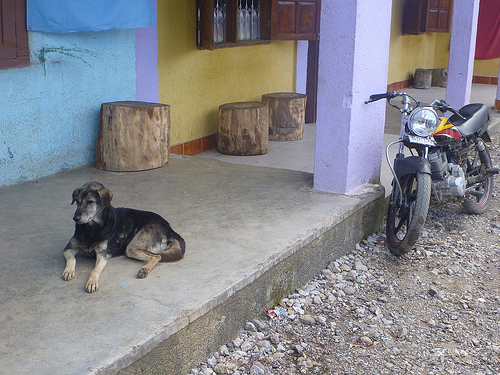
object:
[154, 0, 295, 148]
wall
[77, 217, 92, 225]
mouth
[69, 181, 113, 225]
head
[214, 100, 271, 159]
stump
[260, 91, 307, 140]
stump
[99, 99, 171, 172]
stump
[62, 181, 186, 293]
dog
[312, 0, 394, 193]
post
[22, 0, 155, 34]
curtain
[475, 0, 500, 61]
red curtain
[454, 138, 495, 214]
tire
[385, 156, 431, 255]
tire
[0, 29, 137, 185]
wall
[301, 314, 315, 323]
rocks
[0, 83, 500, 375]
porch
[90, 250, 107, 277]
leg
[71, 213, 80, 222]
nose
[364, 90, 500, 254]
motorcycle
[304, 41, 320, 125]
door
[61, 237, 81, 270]
leg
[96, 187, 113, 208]
ear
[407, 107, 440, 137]
headlight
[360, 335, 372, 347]
gravel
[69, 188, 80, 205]
ear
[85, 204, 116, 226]
neck